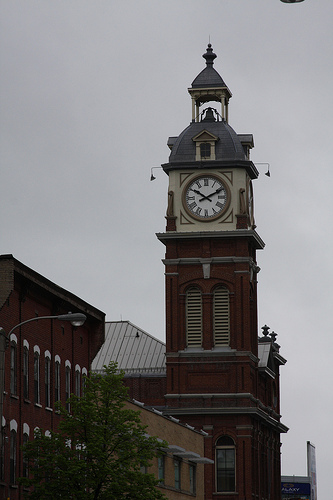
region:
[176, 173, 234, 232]
clock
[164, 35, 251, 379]
clock tower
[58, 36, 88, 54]
white clouds in blue sky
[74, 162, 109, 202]
white clouds in blue sky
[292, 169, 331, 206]
white clouds in blue sky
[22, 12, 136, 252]
The sky is the color gray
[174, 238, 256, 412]
The building is the color brown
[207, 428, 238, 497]
The window on the side of the building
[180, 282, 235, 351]
The vents on the side of the building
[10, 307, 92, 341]
The street light on the street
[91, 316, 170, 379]
The roof of the building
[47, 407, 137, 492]
The leaves on the tree are green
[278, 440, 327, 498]
The building is are the color white and blue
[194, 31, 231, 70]
top of the tower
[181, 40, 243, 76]
top of the pillar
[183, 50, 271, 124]
top of the building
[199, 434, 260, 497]
a small window in the building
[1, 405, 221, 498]
a series of windows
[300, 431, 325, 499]
a wall near building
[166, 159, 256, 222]
a clock on top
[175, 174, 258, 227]
a clock on tower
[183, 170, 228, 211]
a clock on builidng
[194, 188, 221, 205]
hands of the clock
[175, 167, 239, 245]
a white clock on a building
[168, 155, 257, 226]
a round clock on a building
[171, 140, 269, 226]
a big clock on a building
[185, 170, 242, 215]
the hands on a clock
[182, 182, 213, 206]
the small hand on a clock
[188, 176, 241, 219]
the big hand on a clock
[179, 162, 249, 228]
numbers on a clock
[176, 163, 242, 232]
the black hands on a clock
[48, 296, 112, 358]
the light near a clock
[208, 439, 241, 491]
window of a building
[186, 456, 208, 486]
window of a building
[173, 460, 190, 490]
window of a building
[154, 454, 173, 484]
window of a building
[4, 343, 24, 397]
window of a building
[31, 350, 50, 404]
window of a building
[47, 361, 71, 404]
window of a building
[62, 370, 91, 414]
window of a building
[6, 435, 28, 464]
window of a building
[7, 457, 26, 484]
window of a building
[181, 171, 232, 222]
a clock on a tower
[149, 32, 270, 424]
a pointed clock tower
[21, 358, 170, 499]
a tree in front of some buildings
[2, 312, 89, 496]
a curved street light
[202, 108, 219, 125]
a bell in a tower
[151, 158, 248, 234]
clock on the building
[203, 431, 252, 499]
window on the building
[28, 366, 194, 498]
tree next to the building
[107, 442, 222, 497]
many windows on building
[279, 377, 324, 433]
sky above the land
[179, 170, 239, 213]
arms on the clock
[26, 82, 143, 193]
sky above the land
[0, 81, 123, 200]
gray sky above building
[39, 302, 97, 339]
lamp above the ground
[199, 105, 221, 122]
a lone bell in a belfry